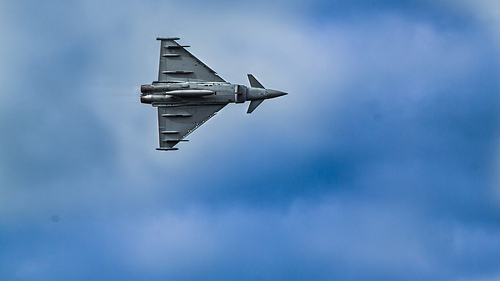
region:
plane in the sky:
[129, 23, 304, 164]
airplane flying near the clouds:
[103, 18, 306, 173]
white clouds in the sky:
[1, 3, 497, 280]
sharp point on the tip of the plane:
[269, 82, 296, 102]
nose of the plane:
[262, 74, 303, 112]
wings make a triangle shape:
[147, 32, 235, 156]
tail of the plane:
[136, 71, 154, 109]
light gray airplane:
[121, 23, 313, 155]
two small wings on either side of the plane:
[246, 66, 268, 118]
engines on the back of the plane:
[137, 82, 151, 104]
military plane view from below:
[135, 25, 294, 154]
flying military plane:
[128, 31, 294, 160]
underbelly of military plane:
[131, 33, 296, 156]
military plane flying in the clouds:
[135, 31, 296, 158]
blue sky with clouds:
[113, 164, 488, 276]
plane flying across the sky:
[128, 31, 300, 163]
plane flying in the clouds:
[131, 33, 296, 153]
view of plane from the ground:
[131, 28, 291, 158]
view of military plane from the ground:
[130, 30, 290, 157]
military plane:
[131, 33, 293, 159]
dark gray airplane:
[124, 12, 304, 168]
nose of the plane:
[239, 71, 296, 114]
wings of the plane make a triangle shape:
[140, 23, 236, 161]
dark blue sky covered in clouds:
[3, 0, 499, 278]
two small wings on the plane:
[246, 67, 264, 114]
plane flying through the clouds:
[129, 21, 296, 168]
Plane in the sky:
[138, 36, 288, 153]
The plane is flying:
[138, 37, 287, 150]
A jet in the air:
[140, 37, 287, 151]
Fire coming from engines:
[77, 81, 140, 103]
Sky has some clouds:
[0, 1, 496, 280]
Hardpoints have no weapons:
[160, 36, 194, 151]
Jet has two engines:
[138, 84, 170, 104]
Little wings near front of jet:
[247, 72, 261, 113]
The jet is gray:
[141, 36, 286, 150]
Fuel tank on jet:
[165, 89, 215, 94]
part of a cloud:
[271, 126, 336, 214]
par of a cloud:
[286, 144, 344, 221]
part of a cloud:
[257, 110, 312, 202]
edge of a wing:
[174, 100, 230, 167]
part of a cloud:
[306, 128, 343, 183]